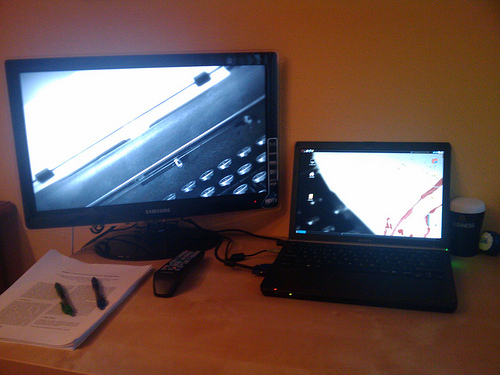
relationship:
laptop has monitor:
[244, 110, 474, 330] [6, 44, 288, 261]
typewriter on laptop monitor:
[308, 157, 440, 244] [269, 135, 471, 308]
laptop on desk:
[244, 110, 474, 330] [19, 202, 499, 372]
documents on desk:
[2, 233, 149, 365] [28, 191, 491, 367]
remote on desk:
[153, 246, 203, 296] [1, 227, 497, 374]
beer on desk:
[447, 194, 488, 260] [1, 227, 497, 374]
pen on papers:
[90, 275, 107, 310] [1, 245, 156, 352]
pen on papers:
[53, 280, 73, 315] [1, 245, 156, 352]